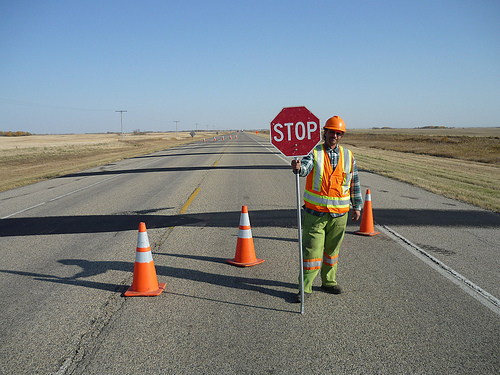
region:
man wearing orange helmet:
[331, 120, 341, 125]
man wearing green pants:
[314, 224, 321, 245]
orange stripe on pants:
[312, 254, 320, 265]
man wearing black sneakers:
[321, 280, 346, 297]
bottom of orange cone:
[226, 256, 266, 271]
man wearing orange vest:
[331, 180, 338, 192]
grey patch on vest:
[316, 168, 323, 180]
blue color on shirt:
[353, 185, 362, 195]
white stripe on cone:
[365, 194, 372, 201]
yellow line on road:
[185, 192, 197, 209]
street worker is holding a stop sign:
[259, 76, 364, 331]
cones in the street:
[118, 181, 377, 307]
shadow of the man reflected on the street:
[42, 246, 302, 308]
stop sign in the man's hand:
[270, 102, 317, 322]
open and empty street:
[0, 128, 496, 373]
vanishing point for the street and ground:
[227, 126, 252, 136]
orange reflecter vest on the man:
[298, 141, 356, 217]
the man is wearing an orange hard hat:
[322, 111, 349, 136]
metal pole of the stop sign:
[288, 149, 309, 332]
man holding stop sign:
[264, 94, 369, 312]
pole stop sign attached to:
[290, 159, 315, 317]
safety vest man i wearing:
[305, 142, 353, 211]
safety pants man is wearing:
[297, 216, 353, 291]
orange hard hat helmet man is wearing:
[327, 113, 343, 132]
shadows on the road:
[7, 144, 497, 352]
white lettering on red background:
[270, 117, 317, 141]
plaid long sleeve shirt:
[295, 142, 364, 210]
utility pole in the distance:
[113, 104, 130, 134]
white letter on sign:
[271, 121, 288, 148]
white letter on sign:
[283, 118, 295, 140]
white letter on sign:
[296, 119, 306, 144]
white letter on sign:
[306, 114, 318, 144]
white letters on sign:
[271, 118, 318, 145]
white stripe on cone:
[136, 227, 152, 249]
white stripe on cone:
[132, 249, 154, 265]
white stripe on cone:
[238, 210, 251, 227]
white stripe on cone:
[235, 226, 255, 246]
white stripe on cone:
[361, 192, 372, 201]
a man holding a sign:
[275, 96, 347, 325]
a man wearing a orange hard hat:
[321, 121, 356, 146]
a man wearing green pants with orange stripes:
[286, 203, 348, 306]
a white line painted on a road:
[377, 191, 494, 336]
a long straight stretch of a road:
[143, 121, 258, 246]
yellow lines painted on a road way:
[166, 132, 237, 239]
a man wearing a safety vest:
[274, 143, 356, 229]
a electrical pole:
[107, 99, 134, 144]